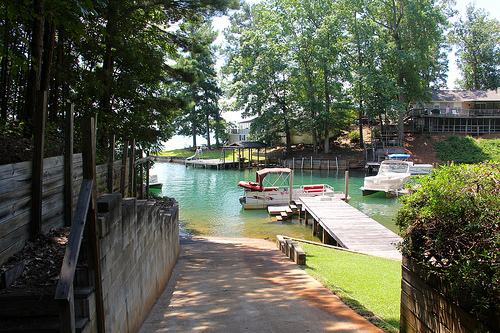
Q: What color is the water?
A: Blue.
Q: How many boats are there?
A: 2.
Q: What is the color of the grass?
A: Green.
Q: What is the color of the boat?
A: Mainly white.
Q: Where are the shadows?
A: In the ground.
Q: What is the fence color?
A: Brown.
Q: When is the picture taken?
A: Daytime.